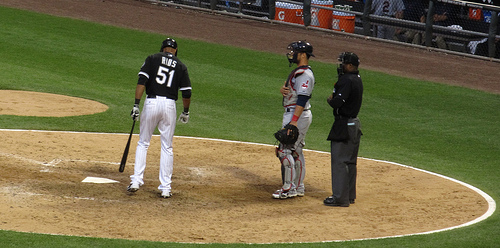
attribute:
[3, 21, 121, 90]
grass — green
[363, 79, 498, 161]
grass — green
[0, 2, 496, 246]
grass — green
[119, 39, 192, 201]
guy — wearing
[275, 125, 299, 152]
catchers glove — black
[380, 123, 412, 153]
ground — grassy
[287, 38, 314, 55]
helmet — black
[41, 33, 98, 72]
grass — green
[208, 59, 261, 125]
grass — green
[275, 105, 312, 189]
pants — grey, red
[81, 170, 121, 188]
home plate — white